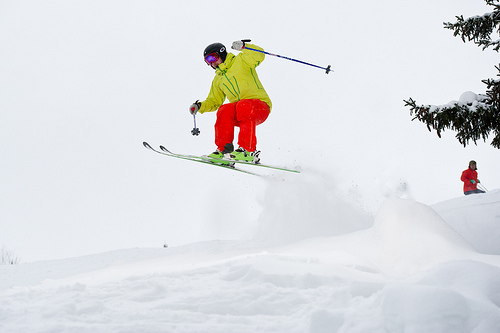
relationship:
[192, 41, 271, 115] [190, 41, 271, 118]
girls jacket yellow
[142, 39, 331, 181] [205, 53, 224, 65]
man wearing goggles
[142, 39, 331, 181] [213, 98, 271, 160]
man wearing pants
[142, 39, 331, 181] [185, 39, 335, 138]
man holding poles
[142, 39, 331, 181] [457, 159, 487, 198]
man being man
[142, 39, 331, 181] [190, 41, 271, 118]
man wearing jacket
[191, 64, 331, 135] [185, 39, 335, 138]
prongs ski pole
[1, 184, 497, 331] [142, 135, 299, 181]
snow behind skis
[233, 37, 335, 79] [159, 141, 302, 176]
pole parallel ski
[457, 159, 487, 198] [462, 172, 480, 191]
man orange jacket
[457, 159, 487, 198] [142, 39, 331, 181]
man watching man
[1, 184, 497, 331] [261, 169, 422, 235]
snow kicked up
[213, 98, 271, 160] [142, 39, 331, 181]
orange pants man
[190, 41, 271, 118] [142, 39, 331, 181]
yellow jacket man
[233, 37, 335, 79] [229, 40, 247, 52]
pole in hand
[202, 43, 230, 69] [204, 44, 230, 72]
black helmet head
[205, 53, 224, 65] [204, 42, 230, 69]
goggles on face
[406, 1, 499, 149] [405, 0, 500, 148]
snow on branch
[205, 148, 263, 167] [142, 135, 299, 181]
yellow boots skis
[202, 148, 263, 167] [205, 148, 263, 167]
neon green boots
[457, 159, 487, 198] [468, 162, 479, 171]
man jacket hat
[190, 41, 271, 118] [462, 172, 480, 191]
yellow green jacket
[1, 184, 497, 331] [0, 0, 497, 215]
snow flying air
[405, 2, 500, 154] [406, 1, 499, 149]
evergreen branches snow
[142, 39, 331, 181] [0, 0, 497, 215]
man jumping air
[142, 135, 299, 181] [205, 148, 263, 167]
skis mans feet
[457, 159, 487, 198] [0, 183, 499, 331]
man standing hill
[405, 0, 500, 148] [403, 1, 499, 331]
tree side hill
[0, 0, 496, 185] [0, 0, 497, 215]
grey sky above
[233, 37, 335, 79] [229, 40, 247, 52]
pole man holding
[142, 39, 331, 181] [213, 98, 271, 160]
man's red pants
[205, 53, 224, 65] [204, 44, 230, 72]
goggles mans head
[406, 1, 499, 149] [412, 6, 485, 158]
snow on tree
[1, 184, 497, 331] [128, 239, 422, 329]
snow on ground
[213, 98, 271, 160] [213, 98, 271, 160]
legs in orange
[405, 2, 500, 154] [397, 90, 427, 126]
evergreen has tips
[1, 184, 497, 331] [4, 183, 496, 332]
snow on mountain